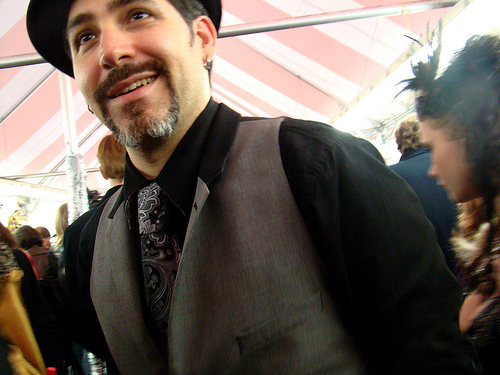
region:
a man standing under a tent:
[25, 0, 462, 372]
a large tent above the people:
[0, 0, 485, 207]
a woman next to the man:
[410, 33, 498, 364]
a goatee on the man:
[96, 58, 180, 144]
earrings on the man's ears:
[86, 53, 214, 115]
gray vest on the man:
[88, 121, 363, 373]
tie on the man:
[134, 181, 182, 341]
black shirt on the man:
[66, 98, 462, 373]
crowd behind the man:
[2, 118, 456, 373]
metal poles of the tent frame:
[0, 2, 465, 223]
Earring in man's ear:
[205, 60, 213, 70]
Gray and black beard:
[116, 126, 173, 147]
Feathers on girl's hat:
[388, 16, 441, 99]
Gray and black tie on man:
[135, 183, 175, 332]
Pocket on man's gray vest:
[237, 292, 325, 347]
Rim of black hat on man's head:
[17, 0, 223, 73]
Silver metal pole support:
[220, 0, 456, 40]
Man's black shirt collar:
[92, 97, 243, 218]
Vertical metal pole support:
[55, 69, 87, 224]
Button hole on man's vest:
[192, 201, 199, 211]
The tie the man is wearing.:
[142, 177, 179, 312]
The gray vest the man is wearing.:
[53, 166, 355, 373]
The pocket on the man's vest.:
[220, 288, 323, 355]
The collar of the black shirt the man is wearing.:
[102, 151, 208, 214]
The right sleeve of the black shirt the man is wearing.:
[296, 132, 463, 362]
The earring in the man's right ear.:
[205, 50, 212, 77]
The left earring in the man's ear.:
[80, 103, 92, 110]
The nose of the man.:
[91, 39, 133, 64]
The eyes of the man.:
[70, 4, 160, 44]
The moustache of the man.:
[86, 57, 168, 85]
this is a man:
[76, 49, 333, 352]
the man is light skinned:
[174, 61, 206, 89]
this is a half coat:
[227, 278, 269, 348]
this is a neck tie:
[137, 213, 183, 305]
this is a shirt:
[342, 194, 402, 257]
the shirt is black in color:
[348, 170, 376, 230]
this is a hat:
[23, 3, 61, 42]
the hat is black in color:
[25, 20, 68, 67]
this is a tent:
[281, 15, 358, 94]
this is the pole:
[265, 15, 317, 58]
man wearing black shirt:
[18, 10, 467, 367]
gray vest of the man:
[95, 124, 358, 372]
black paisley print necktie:
[131, 179, 171, 370]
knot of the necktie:
[133, 193, 170, 232]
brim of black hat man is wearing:
[19, 4, 229, 71]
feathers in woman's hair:
[402, 27, 438, 97]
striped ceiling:
[1, 4, 409, 189]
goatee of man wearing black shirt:
[92, 59, 188, 151]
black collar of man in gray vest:
[100, 101, 222, 216]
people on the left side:
[3, 181, 108, 369]